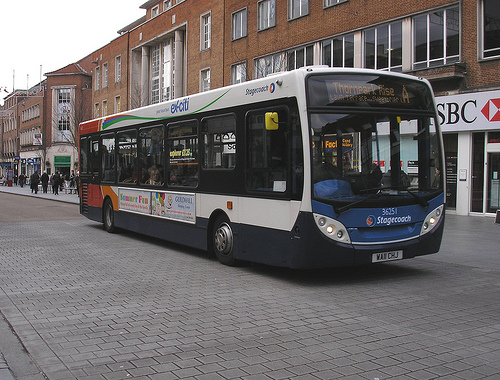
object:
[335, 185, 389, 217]
window wiper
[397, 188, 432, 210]
window wiper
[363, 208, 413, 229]
writing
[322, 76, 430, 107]
sign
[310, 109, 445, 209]
windshield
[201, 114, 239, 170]
windows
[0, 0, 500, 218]
buildings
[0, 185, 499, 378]
road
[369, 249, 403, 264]
license plate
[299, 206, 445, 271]
bumper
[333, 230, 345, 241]
headlights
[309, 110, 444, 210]
window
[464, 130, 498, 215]
door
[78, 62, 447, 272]
bus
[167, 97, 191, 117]
writing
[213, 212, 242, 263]
wheel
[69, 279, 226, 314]
concrete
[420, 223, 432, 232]
light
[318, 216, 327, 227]
front lights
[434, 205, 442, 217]
front lights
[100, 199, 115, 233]
tire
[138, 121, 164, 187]
window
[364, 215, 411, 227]
logo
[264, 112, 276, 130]
side mirror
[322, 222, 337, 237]
headlight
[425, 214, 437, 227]
headlight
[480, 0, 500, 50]
windows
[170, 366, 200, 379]
bricks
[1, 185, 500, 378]
ground